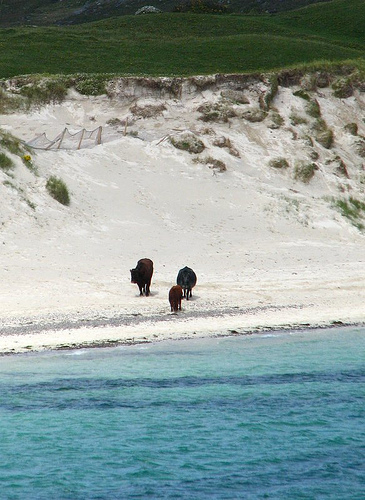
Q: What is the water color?
A: Blue.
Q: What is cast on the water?
A: Shadow.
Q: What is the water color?
A: Green.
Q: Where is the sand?
A: Hillside.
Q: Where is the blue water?
A: Sea.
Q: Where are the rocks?
A: Hill side.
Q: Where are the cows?
A: On the beach.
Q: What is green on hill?
A: Grass.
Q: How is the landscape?
A: Hilly.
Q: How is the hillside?
A: Snow covered.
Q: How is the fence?
A: Falling.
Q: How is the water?
A: Wavy.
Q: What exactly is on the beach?
A: Animals.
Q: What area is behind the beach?
A: Grass.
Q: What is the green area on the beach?
A: Grass.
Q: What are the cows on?
A: Snow.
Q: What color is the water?
A: Blue.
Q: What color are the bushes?
A: Green.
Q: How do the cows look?
A: Peaceful.